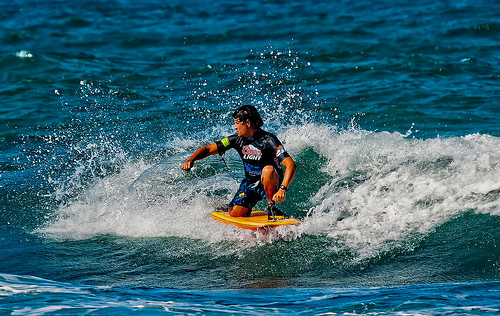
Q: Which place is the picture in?
A: It is at the sea.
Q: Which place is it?
A: It is a sea.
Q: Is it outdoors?
A: Yes, it is outdoors.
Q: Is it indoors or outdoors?
A: It is outdoors.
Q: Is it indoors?
A: No, it is outdoors.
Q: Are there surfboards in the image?
A: Yes, there is a surfboard.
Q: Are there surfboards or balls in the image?
A: Yes, there is a surfboard.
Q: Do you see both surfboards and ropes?
A: No, there is a surfboard but no ropes.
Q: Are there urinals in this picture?
A: No, there are no urinals.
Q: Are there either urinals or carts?
A: No, there are no urinals or carts.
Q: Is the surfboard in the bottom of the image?
A: Yes, the surfboard is in the bottom of the image.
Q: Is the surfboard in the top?
A: No, the surfboard is in the bottom of the image.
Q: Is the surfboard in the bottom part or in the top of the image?
A: The surfboard is in the bottom of the image.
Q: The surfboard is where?
A: The surfboard is on the sea.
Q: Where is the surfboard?
A: The surfboard is on the sea.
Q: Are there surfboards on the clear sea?
A: Yes, there is a surfboard on the sea.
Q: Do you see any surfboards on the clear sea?
A: Yes, there is a surfboard on the sea.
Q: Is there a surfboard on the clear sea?
A: Yes, there is a surfboard on the sea.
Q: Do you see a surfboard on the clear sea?
A: Yes, there is a surfboard on the sea.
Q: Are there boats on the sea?
A: No, there is a surfboard on the sea.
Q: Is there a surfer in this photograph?
A: Yes, there is a surfer.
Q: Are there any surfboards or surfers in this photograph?
A: Yes, there is a surfer.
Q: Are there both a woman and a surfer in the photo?
A: No, there is a surfer but no women.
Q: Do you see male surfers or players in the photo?
A: Yes, there is a male surfer.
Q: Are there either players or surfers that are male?
A: Yes, the surfer is male.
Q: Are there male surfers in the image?
A: Yes, there is a male surfer.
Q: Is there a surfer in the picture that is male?
A: Yes, there is a surfer that is male.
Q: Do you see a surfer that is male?
A: Yes, there is a surfer that is male.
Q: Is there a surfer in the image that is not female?
A: Yes, there is a male surfer.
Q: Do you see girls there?
A: No, there are no girls.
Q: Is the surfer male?
A: Yes, the surfer is male.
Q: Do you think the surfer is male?
A: Yes, the surfer is male.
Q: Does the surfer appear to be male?
A: Yes, the surfer is male.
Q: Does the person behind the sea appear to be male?
A: Yes, the surfer is male.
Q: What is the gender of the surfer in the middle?
A: The surfer is male.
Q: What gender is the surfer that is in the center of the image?
A: The surfer is male.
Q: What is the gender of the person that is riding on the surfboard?
A: The surfer is male.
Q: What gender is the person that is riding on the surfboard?
A: The surfer is male.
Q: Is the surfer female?
A: No, the surfer is male.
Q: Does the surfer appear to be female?
A: No, the surfer is male.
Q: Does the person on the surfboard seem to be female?
A: No, the surfer is male.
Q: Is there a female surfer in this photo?
A: No, there is a surfer but he is male.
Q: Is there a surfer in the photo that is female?
A: No, there is a surfer but he is male.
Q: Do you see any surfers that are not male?
A: No, there is a surfer but he is male.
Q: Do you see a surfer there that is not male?
A: No, there is a surfer but he is male.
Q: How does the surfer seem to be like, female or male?
A: The surfer is male.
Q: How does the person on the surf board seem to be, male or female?
A: The surfer is male.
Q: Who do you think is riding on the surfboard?
A: The surfer is riding on the surfboard.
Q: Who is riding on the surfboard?
A: The surfer is riding on the surfboard.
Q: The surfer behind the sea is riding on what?
A: The surfer is riding on the surf board.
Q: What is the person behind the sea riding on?
A: The surfer is riding on the surf board.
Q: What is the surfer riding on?
A: The surfer is riding on the surf board.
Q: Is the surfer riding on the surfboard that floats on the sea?
A: Yes, the surfer is riding on the surfboard.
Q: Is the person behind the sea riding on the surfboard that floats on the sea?
A: Yes, the surfer is riding on the surfboard.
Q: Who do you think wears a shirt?
A: The surfer wears a shirt.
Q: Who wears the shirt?
A: The surfer wears a shirt.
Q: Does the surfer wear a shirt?
A: Yes, the surfer wears a shirt.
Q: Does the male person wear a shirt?
A: Yes, the surfer wears a shirt.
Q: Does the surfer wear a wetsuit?
A: No, the surfer wears a shirt.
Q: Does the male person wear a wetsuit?
A: No, the surfer wears a shirt.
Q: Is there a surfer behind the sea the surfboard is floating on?
A: Yes, there is a surfer behind the sea.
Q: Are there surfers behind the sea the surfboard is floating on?
A: Yes, there is a surfer behind the sea.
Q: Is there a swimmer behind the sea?
A: No, there is a surfer behind the sea.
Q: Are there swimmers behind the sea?
A: No, there is a surfer behind the sea.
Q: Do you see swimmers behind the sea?
A: No, there is a surfer behind the sea.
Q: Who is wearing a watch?
A: The surfer is wearing a watch.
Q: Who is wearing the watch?
A: The surfer is wearing a watch.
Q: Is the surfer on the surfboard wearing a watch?
A: Yes, the surfer is wearing a watch.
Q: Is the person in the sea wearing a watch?
A: Yes, the surfer is wearing a watch.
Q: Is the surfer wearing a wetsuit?
A: No, the surfer is wearing a watch.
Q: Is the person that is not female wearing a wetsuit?
A: No, the surfer is wearing a watch.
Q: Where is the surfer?
A: The surfer is in the sea.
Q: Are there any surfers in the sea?
A: Yes, there is a surfer in the sea.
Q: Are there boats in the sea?
A: No, there is a surfer in the sea.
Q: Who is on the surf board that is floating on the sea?
A: The surfer is on the surf board.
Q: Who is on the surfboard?
A: The surfer is on the surf board.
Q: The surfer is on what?
A: The surfer is on the surfboard.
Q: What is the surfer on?
A: The surfer is on the surfboard.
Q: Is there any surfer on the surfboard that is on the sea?
A: Yes, there is a surfer on the surfboard.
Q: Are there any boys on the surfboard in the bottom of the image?
A: No, there is a surfer on the surf board.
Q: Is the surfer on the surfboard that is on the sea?
A: Yes, the surfer is on the surf board.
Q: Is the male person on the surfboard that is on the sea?
A: Yes, the surfer is on the surf board.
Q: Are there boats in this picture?
A: No, there are no boats.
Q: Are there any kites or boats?
A: No, there are no boats or kites.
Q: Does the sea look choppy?
A: Yes, the sea is choppy.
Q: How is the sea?
A: The sea is choppy.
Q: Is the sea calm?
A: No, the sea is choppy.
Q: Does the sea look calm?
A: No, the sea is choppy.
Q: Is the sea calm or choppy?
A: The sea is choppy.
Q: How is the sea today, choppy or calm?
A: The sea is choppy.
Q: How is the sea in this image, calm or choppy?
A: The sea is choppy.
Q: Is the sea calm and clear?
A: No, the sea is clear but choppy.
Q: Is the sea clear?
A: Yes, the sea is clear.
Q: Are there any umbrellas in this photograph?
A: No, there are no umbrellas.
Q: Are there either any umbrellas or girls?
A: No, there are no umbrellas or girls.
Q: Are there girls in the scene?
A: No, there are no girls.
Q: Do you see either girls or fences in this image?
A: No, there are no girls or fences.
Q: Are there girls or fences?
A: No, there are no girls or fences.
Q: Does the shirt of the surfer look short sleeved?
A: Yes, the shirt is short sleeved.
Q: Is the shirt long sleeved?
A: No, the shirt is short sleeved.